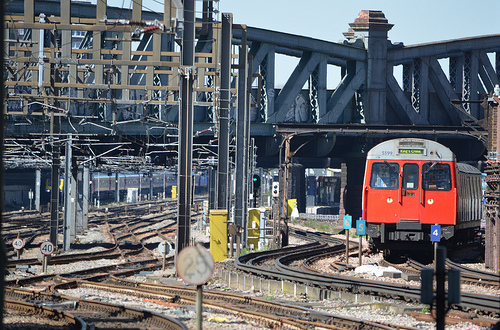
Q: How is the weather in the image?
A: It is clear.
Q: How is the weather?
A: It is clear.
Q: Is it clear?
A: Yes, it is clear.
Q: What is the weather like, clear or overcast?
A: It is clear.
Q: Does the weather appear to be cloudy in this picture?
A: No, it is clear.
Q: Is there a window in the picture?
A: Yes, there is a window.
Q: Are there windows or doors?
A: Yes, there is a window.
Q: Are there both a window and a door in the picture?
A: Yes, there are both a window and a door.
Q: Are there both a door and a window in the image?
A: Yes, there are both a window and a door.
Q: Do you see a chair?
A: No, there are no chairs.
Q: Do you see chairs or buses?
A: No, there are no chairs or buses.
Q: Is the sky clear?
A: Yes, the sky is clear.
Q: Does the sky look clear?
A: Yes, the sky is clear.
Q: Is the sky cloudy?
A: No, the sky is clear.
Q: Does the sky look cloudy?
A: No, the sky is clear.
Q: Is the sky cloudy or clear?
A: The sky is clear.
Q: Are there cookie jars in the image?
A: No, there are no cookie jars.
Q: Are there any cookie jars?
A: No, there are no cookie jars.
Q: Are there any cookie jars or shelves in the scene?
A: No, there are no cookie jars or shelves.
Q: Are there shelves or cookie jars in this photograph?
A: No, there are no cookie jars or shelves.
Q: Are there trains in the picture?
A: Yes, there is a train.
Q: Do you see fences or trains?
A: Yes, there is a train.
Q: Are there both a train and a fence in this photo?
A: No, there is a train but no fences.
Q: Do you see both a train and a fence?
A: No, there is a train but no fences.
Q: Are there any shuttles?
A: No, there are no shuttles.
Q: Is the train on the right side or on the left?
A: The train is on the right of the image.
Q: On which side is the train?
A: The train is on the right of the image.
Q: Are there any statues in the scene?
A: No, there are no statues.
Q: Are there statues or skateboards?
A: No, there are no statues or skateboards.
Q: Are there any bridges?
A: Yes, there is a bridge.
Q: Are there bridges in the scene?
A: Yes, there is a bridge.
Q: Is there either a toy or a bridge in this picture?
A: Yes, there is a bridge.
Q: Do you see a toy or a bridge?
A: Yes, there is a bridge.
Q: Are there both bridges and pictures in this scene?
A: No, there is a bridge but no pictures.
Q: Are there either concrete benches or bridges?
A: Yes, there is a concrete bridge.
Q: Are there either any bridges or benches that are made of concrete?
A: Yes, the bridge is made of concrete.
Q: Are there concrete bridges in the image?
A: Yes, there is a bridge that is made of concrete.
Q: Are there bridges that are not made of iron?
A: Yes, there is a bridge that is made of cement.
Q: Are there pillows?
A: No, there are no pillows.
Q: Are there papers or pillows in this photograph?
A: No, there are no pillows or papers.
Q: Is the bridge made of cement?
A: Yes, the bridge is made of cement.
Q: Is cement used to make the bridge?
A: Yes, the bridge is made of cement.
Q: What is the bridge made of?
A: The bridge is made of concrete.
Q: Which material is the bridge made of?
A: The bridge is made of concrete.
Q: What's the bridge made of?
A: The bridge is made of concrete.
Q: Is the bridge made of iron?
A: No, the bridge is made of concrete.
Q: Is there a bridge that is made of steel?
A: No, there is a bridge but it is made of concrete.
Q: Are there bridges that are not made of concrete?
A: No, there is a bridge but it is made of concrete.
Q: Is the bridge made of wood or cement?
A: The bridge is made of cement.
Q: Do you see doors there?
A: Yes, there is a door.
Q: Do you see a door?
A: Yes, there is a door.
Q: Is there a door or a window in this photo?
A: Yes, there is a door.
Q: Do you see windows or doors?
A: Yes, there is a door.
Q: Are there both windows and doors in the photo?
A: Yes, there are both a door and windows.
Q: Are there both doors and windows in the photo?
A: Yes, there are both a door and windows.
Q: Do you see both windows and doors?
A: Yes, there are both a door and windows.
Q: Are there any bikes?
A: No, there are no bikes.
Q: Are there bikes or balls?
A: No, there are no bikes or balls.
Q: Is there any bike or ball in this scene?
A: No, there are no bikes or balls.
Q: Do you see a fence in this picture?
A: No, there are no fences.